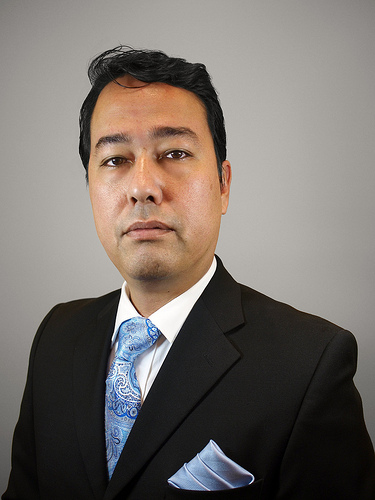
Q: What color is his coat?
A: Black.